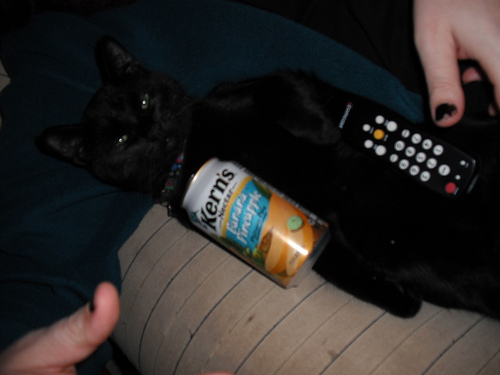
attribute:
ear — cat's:
[46, 132, 78, 155]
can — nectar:
[181, 159, 332, 290]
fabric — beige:
[115, 230, 499, 372]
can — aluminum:
[141, 150, 379, 300]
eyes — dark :
[107, 87, 154, 149]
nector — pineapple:
[165, 148, 332, 293]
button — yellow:
[373, 127, 384, 138]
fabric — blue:
[5, 2, 426, 303]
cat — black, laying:
[39, 39, 497, 321]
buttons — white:
[397, 123, 437, 177]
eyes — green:
[106, 81, 155, 153]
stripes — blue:
[115, 208, 495, 373]